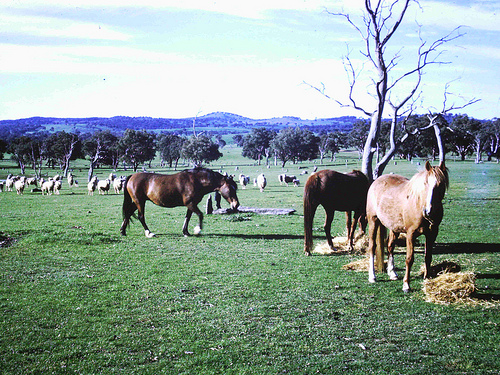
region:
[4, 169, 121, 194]
Lots of sheep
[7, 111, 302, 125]
Rolling hills on horizon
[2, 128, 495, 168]
Grove of trees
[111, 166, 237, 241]
Horse walking toward hay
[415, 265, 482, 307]
Flake of hay on the ground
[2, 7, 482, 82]
Clouds in the sky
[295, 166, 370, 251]
Horse eating some hay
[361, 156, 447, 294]
Horse staring at something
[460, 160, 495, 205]
Puff of smoke floating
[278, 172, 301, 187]
Mother sheep and her lamb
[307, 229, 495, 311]
LOOK LIKE THREE PILES OF HAYS ON THE GREEN GRASS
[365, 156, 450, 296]
ONE LIGHT BROWN HORSE STANDING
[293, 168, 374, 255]
THE DARK BROWN HORSE IS EATING THE HAY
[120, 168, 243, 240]
THE OTHER DARK BROWN HORSE IS TROTTING ALONG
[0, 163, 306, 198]
THERE IS A LOT OF SHEEP,S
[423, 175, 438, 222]
THE HORSE HAVE A WHITE FACE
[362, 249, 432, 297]
THE HORSE HAVE WHITE LEGS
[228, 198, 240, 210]
THE HORSE HAVE WHITE MOUTH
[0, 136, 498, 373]
THE ANIMALS IS IN A GREEN PASTURE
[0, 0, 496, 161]
THERE IS TREES AND BLUE SKY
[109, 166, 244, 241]
a dark brown horse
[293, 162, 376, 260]
a dark brown horse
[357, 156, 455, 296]
a light brown horse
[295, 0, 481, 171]
a barren tree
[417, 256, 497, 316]
a lump of hay on the ground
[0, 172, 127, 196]
a herd of sheep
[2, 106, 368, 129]
a hillside off in the distance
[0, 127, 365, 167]
a row of trees in the distance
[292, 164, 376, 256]
a horse eating hay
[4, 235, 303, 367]
a green pasture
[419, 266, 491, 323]
small pile of hay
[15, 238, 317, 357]
portion of freshly cut grass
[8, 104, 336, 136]
beautiful mountain range vista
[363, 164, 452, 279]
beautiful light brown mare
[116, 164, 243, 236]
majestic black mare strutting across the field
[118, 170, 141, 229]
beautiful horse's tail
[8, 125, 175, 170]
cluster of green trees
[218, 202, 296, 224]
large gray stone watering hole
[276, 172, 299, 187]
black cow with white tail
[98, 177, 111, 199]
an all white colored sheep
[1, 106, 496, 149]
green hills in background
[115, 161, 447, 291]
three brown horses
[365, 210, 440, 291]
the horse has four legs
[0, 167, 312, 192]
white sheep standing behind horses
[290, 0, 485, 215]
tall tree without leaves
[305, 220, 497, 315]
piles of hay on ground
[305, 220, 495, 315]
the hay is brown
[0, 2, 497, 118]
blue sky with puffy white clouds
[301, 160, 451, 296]
two horses standing together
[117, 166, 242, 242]
brown horse with black tail